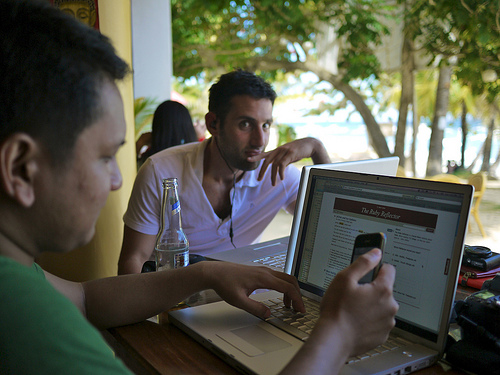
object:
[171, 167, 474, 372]
laptop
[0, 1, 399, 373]
man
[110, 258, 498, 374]
table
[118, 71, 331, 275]
man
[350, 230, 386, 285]
cell phone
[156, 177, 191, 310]
bottle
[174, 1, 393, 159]
tree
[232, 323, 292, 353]
touchpad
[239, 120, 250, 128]
eye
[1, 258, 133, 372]
shirt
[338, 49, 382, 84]
leaves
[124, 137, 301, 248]
shirt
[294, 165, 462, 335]
screen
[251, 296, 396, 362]
keyboard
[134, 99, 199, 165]
woman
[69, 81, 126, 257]
face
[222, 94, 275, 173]
face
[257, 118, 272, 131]
eyes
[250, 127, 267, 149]
nose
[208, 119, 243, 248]
headphones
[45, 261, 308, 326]
arm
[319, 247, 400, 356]
hand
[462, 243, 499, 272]
camera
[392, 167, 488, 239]
chairs